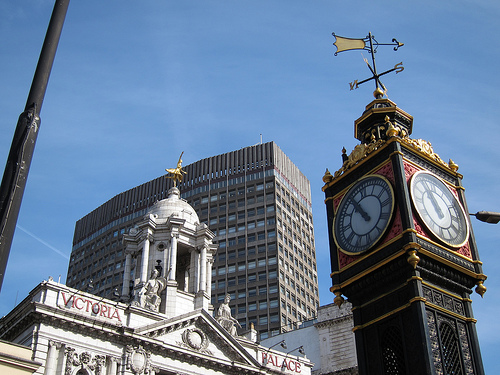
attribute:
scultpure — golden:
[164, 149, 188, 186]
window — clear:
[227, 227, 237, 238]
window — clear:
[242, 222, 258, 232]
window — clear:
[255, 222, 269, 231]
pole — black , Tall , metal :
[10, 1, 90, 184]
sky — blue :
[6, 14, 467, 184]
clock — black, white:
[332, 175, 397, 251]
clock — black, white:
[412, 165, 471, 237]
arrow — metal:
[330, 31, 407, 55]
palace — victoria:
[0, 152, 312, 373]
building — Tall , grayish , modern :
[188, 143, 333, 340]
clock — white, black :
[400, 159, 475, 256]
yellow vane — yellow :
[329, 21, 392, 63]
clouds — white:
[118, 96, 226, 119]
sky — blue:
[67, 35, 494, 112]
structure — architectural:
[110, 147, 220, 318]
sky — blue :
[135, 30, 303, 97]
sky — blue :
[1, 0, 496, 374]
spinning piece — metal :
[331, 29, 405, 99]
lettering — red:
[57, 289, 127, 326]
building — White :
[4, 149, 318, 373]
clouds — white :
[38, 65, 221, 159]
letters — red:
[58, 285, 121, 325]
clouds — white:
[137, 45, 214, 109]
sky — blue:
[128, 106, 263, 123]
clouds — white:
[129, 54, 275, 165]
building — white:
[56, 302, 307, 372]